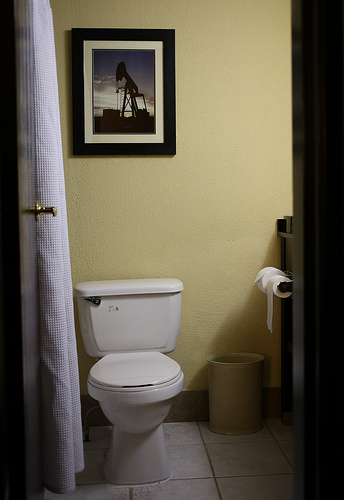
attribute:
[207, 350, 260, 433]
can — round, white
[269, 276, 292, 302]
toilet paper — two rolls, unwraveled, hanging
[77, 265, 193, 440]
toilet — white, porcelain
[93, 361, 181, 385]
seat — down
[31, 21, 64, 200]
curtain — blue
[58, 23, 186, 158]
picture — framed, black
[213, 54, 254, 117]
wall — yellow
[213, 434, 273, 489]
tiles — white, light, grey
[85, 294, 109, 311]
handle — small, metal, dark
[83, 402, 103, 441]
wire — metal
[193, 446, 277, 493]
tiling — dirty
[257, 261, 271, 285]
roll — large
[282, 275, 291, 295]
holders — metal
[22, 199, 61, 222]
doorknob — brass, gray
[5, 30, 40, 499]
door — white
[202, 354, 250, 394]
trash can — tan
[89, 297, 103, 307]
toilet handle — black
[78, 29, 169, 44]
frame — black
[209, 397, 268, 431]
wastebasket — brown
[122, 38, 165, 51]
border — white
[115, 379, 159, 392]
lid — closed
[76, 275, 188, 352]
toilet tank — white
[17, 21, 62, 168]
shower curtain — white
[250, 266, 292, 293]
toilet rolls — white